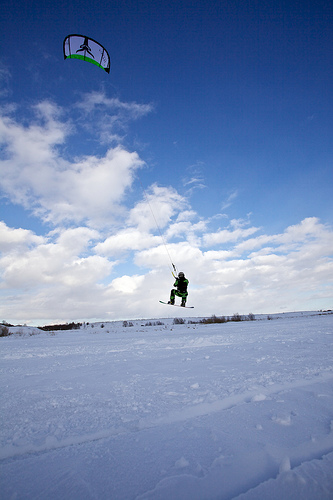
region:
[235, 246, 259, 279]
white clouds in sky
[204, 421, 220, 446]
white ice on ground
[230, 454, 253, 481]
white ice on ground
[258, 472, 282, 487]
white ice on ground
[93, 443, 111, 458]
white ice on ground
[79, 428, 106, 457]
white ice on ground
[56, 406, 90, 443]
white ice on ground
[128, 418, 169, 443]
white ice on ground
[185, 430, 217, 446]
white ice on ground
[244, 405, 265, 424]
white ice on ground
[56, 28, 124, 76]
kite in the air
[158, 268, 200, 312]
man on a snowboard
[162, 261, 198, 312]
man in the air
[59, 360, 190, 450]
the snow is white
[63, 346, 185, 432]
the snow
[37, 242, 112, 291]
the clouds are white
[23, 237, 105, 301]
the clouds in the sky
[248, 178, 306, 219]
the sky is clear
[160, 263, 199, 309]
person is holding the kite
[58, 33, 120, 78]
the kite is flying high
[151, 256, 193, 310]
man doing tricks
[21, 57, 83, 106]
white clouds in blue sky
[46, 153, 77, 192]
white clouds in blue sky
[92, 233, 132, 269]
white clouds in blue sky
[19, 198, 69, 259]
white clouds in blue sky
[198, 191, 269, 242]
white clouds in blue sky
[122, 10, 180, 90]
white clouds in blue sky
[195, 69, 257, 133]
white clouds in blue sky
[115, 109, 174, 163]
white clouds in blue sky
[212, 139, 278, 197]
white clouds in blue sky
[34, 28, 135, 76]
kite in the air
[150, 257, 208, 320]
person in the air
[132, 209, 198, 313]
person holding a rope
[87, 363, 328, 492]
markings in the snow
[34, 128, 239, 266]
clouds in the sky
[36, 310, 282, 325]
trees in the distance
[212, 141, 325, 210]
clear blue sky above clouds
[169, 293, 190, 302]
person wearing green pants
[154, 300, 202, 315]
person on ski in the air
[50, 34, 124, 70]
kite is blue and green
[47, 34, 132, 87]
the kite is flying in the air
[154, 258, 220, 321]
the man is flying in the air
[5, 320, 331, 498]
the snow is white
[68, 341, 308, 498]
it was tracks in the snow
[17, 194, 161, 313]
the clouds was white and blue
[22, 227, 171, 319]
the sky looks fluffy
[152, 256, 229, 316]
he is sking in the air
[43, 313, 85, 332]
the trees isin the background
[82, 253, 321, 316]
the man is wearing long sleeve clothes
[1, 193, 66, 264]
the sky is bright